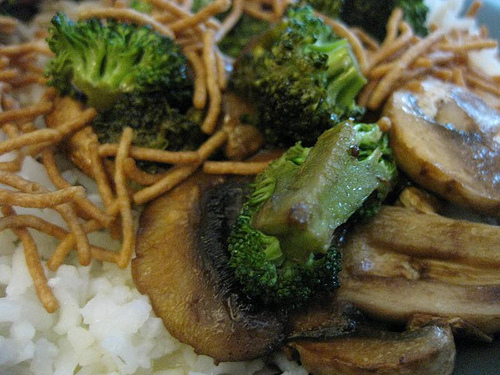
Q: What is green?
A: Broccoli.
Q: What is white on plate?
A: Rice.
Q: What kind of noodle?
A: Chow mein.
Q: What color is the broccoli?
A: Green.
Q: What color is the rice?
A: White.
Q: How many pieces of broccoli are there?
A: 3.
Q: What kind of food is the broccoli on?
A: Mushrooms.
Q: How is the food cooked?
A: Stir fried.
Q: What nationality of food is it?
A: Asian.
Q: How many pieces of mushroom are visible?
A: 3.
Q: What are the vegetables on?
A: Rice.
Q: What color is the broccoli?
A: Green.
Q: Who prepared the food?
A: Chef.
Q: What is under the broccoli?
A: Mushrooms.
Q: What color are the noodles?
A: Brown.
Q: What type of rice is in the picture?
A: White.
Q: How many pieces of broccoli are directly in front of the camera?
A: 3.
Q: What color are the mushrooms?
A: Brown.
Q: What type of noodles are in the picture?
A: Fried noodles.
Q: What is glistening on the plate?
A: A mushroom.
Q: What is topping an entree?
A: Jumble of fried noodles.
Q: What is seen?
A: A piece of broccoli.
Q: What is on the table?
A: A plate of cooked food.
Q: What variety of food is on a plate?
A: Green broccoli.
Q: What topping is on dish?
A: Crunchy.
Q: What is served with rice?
A: Broccoli with mushrooms.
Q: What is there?
A: Food.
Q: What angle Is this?
A: Close-up.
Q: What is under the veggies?
A: White rice.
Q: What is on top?
A: Broccoli.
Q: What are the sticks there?
A: Chow mein.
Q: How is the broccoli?
A: Cooked.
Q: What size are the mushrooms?
A: Big.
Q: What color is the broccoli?
A: Green.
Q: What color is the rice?
A: White.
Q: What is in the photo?
A: Food.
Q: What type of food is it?
A: Broccoli and rice.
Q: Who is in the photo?
A: No one.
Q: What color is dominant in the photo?
A: Green.